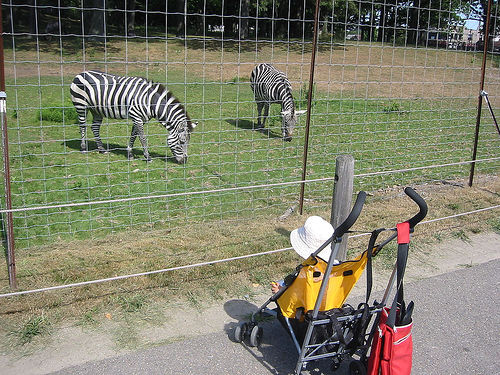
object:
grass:
[3, 165, 80, 224]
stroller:
[234, 186, 429, 374]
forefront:
[15, 203, 494, 300]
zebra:
[70, 70, 200, 165]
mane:
[149, 80, 194, 132]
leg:
[132, 117, 151, 162]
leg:
[75, 104, 89, 154]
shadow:
[61, 139, 178, 163]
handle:
[404, 186, 428, 228]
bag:
[366, 222, 413, 374]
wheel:
[235, 322, 264, 346]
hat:
[290, 215, 335, 260]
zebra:
[249, 63, 307, 142]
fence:
[0, 0, 500, 254]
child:
[270, 215, 341, 294]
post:
[298, 0, 323, 215]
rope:
[0, 157, 499, 214]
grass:
[41, 251, 97, 298]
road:
[42, 256, 499, 375]